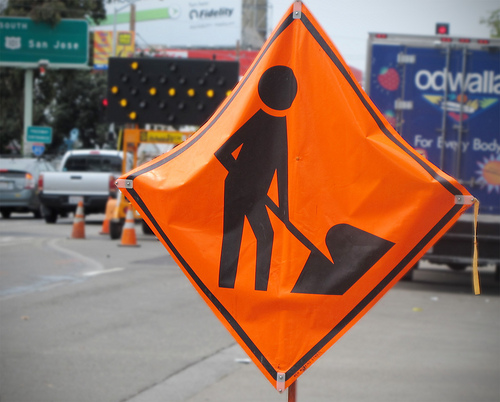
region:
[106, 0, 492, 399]
Sign is orange and black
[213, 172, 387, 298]
The sign is a man holding a shovel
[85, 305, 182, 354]
The pavement is smoother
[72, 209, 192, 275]
Orange cones on the road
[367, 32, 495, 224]
Back of the truck on the road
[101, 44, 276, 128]
Sign with a yellow arrow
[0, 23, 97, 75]
The road sign is green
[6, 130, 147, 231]
Cars waiting at the light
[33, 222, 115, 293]
Scratch on the pavement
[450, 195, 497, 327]
Ribbon hanging of the sign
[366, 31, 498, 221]
blue truck that says Odwalla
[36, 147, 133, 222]
small white pick up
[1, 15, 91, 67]
green road sign that says San Jose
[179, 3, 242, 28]
white banner that says Fidelity in blue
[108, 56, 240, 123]
black sign with orange lights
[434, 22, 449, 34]
red street light above blue truck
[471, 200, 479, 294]
orange ribbon hanging from the sign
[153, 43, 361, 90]
red roof of building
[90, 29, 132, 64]
orange and yellow billboard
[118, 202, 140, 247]
orange traffic cone with white stripes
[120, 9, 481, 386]
an orange traffic flag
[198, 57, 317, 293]
black figure on an orange sign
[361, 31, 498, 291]
back of a blue truck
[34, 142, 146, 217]
back of a silver truck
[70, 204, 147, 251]
several traffic cones on the ground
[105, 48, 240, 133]
a black sign with a yellow arrow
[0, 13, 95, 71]
a green and white sign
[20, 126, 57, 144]
a freeway entrance sign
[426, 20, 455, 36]
a red light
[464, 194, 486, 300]
orange ribbon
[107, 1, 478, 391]
a traffic sign on the street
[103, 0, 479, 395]
traffic sign is orange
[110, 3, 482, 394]
border of traffic sign is black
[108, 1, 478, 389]
traffic sign of construction road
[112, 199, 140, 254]
a cone on the street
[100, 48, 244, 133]
an arrow traffic sign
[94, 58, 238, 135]
arrow pointing to the left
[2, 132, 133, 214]
cars are parking in front of buildings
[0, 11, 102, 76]
a green board on top the store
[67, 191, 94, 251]
an orange cone on road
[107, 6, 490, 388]
an orange traffic sign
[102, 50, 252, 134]
digital black board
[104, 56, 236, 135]
a yellow arrow on the black board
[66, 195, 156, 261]
traffic cones on the ground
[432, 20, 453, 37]
a red traffic light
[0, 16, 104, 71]
a green and white traffic sign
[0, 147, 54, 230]
a gray car stopped in the street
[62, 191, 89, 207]
white license plate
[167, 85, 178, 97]
a yellow light